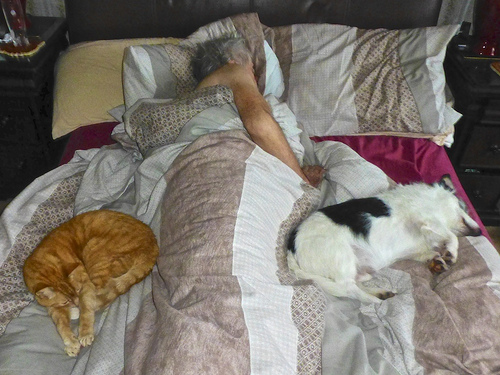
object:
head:
[194, 32, 260, 81]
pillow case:
[123, 21, 470, 145]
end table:
[444, 42, 499, 175]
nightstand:
[0, 13, 50, 106]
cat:
[286, 177, 462, 315]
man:
[152, 31, 322, 375]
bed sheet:
[0, 121, 494, 374]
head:
[35, 281, 95, 318]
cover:
[0, 86, 499, 374]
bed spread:
[0, 127, 498, 373]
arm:
[232, 65, 302, 171]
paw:
[360, 297, 383, 306]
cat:
[18, 207, 159, 358]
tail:
[97, 249, 157, 311]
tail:
[282, 250, 352, 300]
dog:
[287, 176, 482, 299]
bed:
[3, 36, 499, 374]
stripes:
[62, 224, 131, 271]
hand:
[296, 164, 325, 186]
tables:
[4, 3, 483, 216]